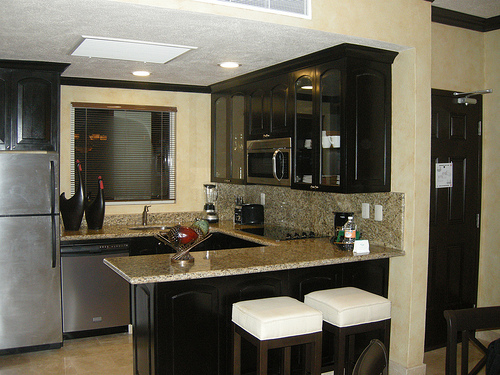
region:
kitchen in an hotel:
[10, 17, 477, 352]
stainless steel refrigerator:
[2, 140, 79, 352]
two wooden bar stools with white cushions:
[218, 250, 419, 374]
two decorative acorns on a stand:
[160, 214, 213, 264]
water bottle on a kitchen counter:
[332, 206, 359, 251]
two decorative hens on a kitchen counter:
[61, 151, 118, 235]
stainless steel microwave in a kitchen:
[245, 113, 307, 191]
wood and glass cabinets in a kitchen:
[198, 53, 381, 188]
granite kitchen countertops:
[122, 240, 347, 270]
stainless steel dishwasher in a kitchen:
[50, 221, 141, 328]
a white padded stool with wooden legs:
[231, 296, 323, 373]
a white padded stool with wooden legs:
[306, 286, 391, 373]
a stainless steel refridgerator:
[1, 148, 63, 348]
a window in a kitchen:
[72, 101, 175, 202]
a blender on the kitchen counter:
[203, 183, 217, 220]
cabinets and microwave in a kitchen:
[210, 41, 397, 193]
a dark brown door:
[425, 90, 483, 356]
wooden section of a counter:
[131, 283, 226, 373]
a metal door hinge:
[453, 87, 492, 111]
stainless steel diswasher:
[60, 243, 132, 335]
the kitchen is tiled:
[47, 104, 358, 369]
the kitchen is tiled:
[96, 187, 256, 368]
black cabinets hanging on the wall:
[207, 40, 400, 192]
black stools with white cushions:
[227, 284, 393, 374]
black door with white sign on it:
[425, 85, 481, 351]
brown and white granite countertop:
[57, 181, 407, 284]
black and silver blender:
[197, 182, 222, 226]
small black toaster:
[239, 202, 268, 227]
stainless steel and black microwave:
[242, 133, 297, 190]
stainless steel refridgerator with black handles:
[0, 150, 64, 360]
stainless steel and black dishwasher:
[57, 240, 133, 340]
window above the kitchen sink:
[65, 97, 180, 205]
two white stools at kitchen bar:
[193, 300, 405, 350]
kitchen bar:
[93, 259, 432, 284]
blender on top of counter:
[193, 172, 230, 235]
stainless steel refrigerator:
[1, 214, 99, 362]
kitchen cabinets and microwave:
[166, 75, 393, 187]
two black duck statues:
[58, 162, 127, 236]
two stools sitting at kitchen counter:
[221, 272, 392, 324]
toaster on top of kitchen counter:
[218, 192, 302, 232]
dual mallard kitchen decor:
[43, 157, 123, 233]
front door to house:
[440, 95, 498, 285]